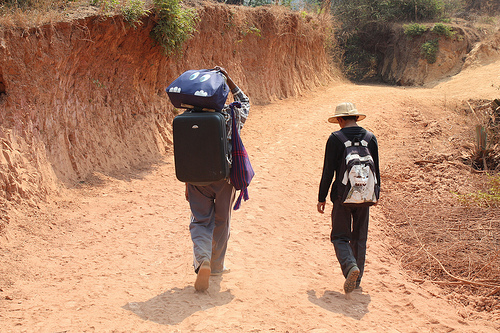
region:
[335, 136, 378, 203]
a white and black backpack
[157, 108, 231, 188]
a dark black suitcase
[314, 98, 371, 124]
a tan straw hat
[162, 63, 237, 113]
a tote bag with eyes and hands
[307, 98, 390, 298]
a person wearing a hat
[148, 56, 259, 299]
a person with a tote bag on his head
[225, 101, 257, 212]
a blue and red striped shoulder bag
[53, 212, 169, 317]
a brown dirt pathway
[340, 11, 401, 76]
green plants in the distance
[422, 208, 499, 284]
dried up sticks and dead plants on the ground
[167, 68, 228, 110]
a luggage with a face painted on it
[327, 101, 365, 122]
a tan wide brimmed hat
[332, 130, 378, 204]
a black and white backpack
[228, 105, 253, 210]
a purple shoulder bag hanging on the right shoulder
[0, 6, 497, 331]
a orange clay dirt road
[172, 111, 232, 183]
a hard shell carry on luggage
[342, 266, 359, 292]
the bottom tread of a hiking boot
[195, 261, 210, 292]
smooth rubber soles of a walking shoe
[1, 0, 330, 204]
a man made cut out area of the road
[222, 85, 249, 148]
the man is wearing a long sleave plaid shirt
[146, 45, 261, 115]
the man on the left has a suitcase on his head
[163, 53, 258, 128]
the suitcase has eyes on it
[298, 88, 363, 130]
the man on the right has on a straw hat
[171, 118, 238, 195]
the man has a suitcase on his back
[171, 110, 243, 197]
the suitcase is black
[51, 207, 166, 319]
the road is of red dirt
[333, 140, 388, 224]
the backpack is black and white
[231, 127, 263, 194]
the man carries a purple tote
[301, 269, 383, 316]
the man's shadow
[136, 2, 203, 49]
a green bush off the road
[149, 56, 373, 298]
two people on dirt path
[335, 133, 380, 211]
backpack being worn by man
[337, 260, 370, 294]
bottom of walker's show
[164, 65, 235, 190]
two pieces of luggage on man's back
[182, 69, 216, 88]
cartoon eyes on luggage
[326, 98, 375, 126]
tan hat with brim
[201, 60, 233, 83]
hand holding onto luggage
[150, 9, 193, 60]
vegetation hanging over ledge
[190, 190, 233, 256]
baggy pants of walker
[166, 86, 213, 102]
cartoon feet on luggage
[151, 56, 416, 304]
two men walking along road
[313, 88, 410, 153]
man wearing tan hat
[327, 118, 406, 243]
man wearing black and white backpack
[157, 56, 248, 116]
man carrying bag on his shoulders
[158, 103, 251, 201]
man with pack on his back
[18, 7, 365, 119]
dirt cliff along side of road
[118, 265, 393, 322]
shadows of men walking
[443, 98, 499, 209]
weeds growing beside road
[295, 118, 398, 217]
man wearing long sleeved shirt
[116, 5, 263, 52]
bush hanging off of ridge